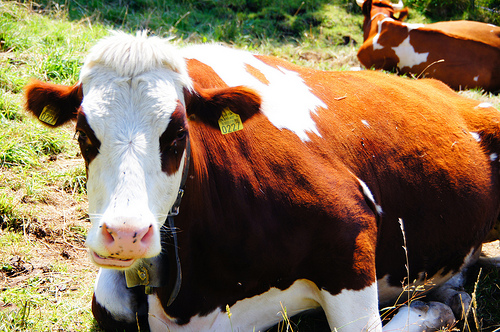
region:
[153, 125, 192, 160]
the eye of a cow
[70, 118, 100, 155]
the eye of a cow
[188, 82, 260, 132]
the ear of a cow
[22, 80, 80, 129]
the eye of a cow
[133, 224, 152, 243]
the nostril of a cow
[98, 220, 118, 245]
the nostril of a cow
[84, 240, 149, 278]
the mouth of a cow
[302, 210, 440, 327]
the leg of a cow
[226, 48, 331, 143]
a white spot on a cow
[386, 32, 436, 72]
a white spot on a cow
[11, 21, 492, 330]
a brown and white cow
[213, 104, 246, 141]
the number 0227 stamped on a tag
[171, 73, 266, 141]
a cow's ear with a yellow tag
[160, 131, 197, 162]
the eye of a cow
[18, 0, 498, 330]
two cows standing on dirt and grass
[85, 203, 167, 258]
a cow's nostrils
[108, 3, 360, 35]
a patch of green grass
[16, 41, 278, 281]
a cow's brown and white head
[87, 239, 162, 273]
a cow's mouth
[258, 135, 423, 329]
the shoulder of a cow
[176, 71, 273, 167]
yellow ear tag on cow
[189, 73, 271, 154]
the cow's number is 0227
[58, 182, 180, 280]
the cow has a pink nose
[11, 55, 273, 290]
the face of a cow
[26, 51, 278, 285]
this cow is white and brown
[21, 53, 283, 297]
the cow has brown eyes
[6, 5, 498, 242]
there are two cows here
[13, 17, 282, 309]
the cow wears a bell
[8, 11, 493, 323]
the cow is laying in the grass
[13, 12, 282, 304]
the fur on top of the cow's head is white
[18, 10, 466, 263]
Picture taken outside.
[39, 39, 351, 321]
Picture taken during the day.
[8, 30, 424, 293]
A large cow in the picture.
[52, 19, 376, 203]
The cow is brown and white.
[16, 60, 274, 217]
The cow has two ear tags.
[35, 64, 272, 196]
The ear tags are yellow.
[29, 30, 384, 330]
The cow is laying down.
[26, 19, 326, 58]
The hills is green.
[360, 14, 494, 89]
Another cow is behind the cow.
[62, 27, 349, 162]
The cow has spots.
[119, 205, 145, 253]
Cow has pink nose.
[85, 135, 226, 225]
Cow has brown fur around eyes.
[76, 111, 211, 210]
Cow has dark eyes.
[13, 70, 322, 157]
Cow has brown ears.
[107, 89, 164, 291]
Cow has white head.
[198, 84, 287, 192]
Yellow tag on cow's ear.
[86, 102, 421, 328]
Cow is brown and white.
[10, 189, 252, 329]
Cow is sitting down on the ground.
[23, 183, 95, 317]
Grass is green and brown.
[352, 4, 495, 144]
Cow behind other cow.